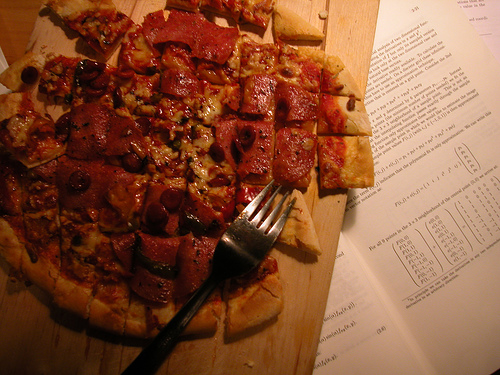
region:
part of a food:
[232, 134, 263, 164]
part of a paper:
[366, 281, 422, 328]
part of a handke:
[131, 288, 207, 368]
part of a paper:
[386, 292, 416, 334]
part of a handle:
[157, 317, 171, 335]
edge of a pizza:
[91, 313, 124, 330]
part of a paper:
[386, 194, 428, 242]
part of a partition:
[349, 253, 414, 307]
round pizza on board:
[32, 53, 356, 324]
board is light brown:
[24, 36, 356, 343]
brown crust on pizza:
[240, 10, 360, 181]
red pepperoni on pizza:
[214, 65, 334, 182]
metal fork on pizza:
[134, 190, 301, 372]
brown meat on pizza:
[61, 65, 219, 195]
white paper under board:
[375, 65, 479, 365]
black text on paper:
[382, 82, 480, 292]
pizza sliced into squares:
[52, 33, 314, 327]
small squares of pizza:
[274, 60, 379, 227]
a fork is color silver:
[101, 176, 306, 371]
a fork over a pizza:
[15, 10, 370, 370]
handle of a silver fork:
[108, 287, 213, 366]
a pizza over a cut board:
[9, 9, 376, 374]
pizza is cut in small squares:
[5, 7, 395, 366]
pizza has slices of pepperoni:
[3, 4, 388, 352]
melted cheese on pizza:
[140, 82, 234, 204]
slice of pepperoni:
[56, 97, 116, 159]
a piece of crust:
[268, 3, 330, 48]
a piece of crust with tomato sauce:
[307, 131, 381, 198]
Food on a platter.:
[2, 2, 378, 370]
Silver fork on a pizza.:
[115, 176, 295, 367]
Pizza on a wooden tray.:
[5, 4, 364, 371]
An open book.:
[275, 2, 498, 368]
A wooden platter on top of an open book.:
[33, 4, 495, 373]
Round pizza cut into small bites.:
[5, 2, 380, 340]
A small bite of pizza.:
[275, 123, 314, 192]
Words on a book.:
[357, 105, 496, 317]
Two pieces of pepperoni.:
[155, 6, 238, 66]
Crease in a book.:
[340, 230, 447, 374]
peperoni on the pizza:
[268, 125, 315, 184]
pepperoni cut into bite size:
[43, 113, 368, 319]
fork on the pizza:
[180, 177, 298, 370]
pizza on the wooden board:
[13, 334, 324, 374]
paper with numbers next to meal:
[371, 113, 499, 370]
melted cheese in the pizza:
[153, 134, 217, 204]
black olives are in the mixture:
[13, 55, 38, 100]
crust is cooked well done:
[35, 299, 294, 350]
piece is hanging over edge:
[312, 138, 374, 193]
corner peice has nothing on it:
[276, 16, 334, 46]